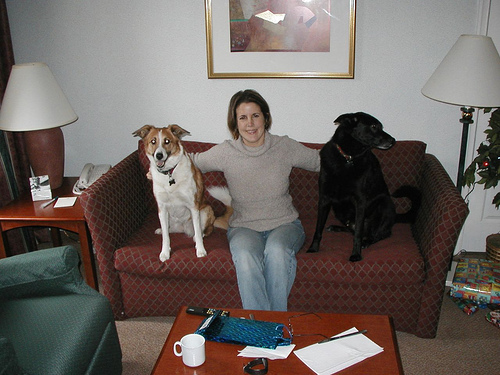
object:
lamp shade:
[0, 62, 79, 131]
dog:
[306, 111, 424, 263]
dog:
[130, 124, 233, 263]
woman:
[186, 89, 323, 311]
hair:
[227, 89, 273, 141]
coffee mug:
[173, 333, 206, 368]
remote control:
[185, 305, 230, 317]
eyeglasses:
[288, 312, 332, 340]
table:
[151, 304, 404, 374]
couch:
[77, 138, 471, 337]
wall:
[0, 0, 481, 186]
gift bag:
[193, 308, 295, 349]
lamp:
[1, 60, 80, 192]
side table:
[1, 176, 99, 292]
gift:
[449, 250, 500, 328]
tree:
[461, 107, 500, 210]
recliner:
[0, 244, 124, 374]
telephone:
[73, 163, 112, 195]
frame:
[204, 0, 358, 80]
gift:
[448, 256, 492, 324]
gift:
[482, 309, 500, 328]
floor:
[80, 256, 499, 374]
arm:
[185, 141, 228, 173]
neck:
[333, 137, 372, 168]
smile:
[245, 128, 259, 135]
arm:
[0, 245, 93, 298]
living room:
[0, 0, 499, 374]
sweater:
[184, 130, 321, 231]